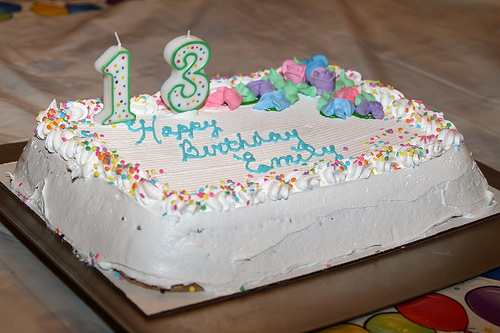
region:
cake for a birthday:
[11, 19, 494, 299]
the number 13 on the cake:
[91, 25, 211, 124]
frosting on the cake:
[233, 220, 367, 249]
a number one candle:
[91, 29, 139, 129]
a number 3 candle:
[158, 30, 216, 116]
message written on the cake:
[123, 113, 353, 171]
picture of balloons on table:
[363, 277, 499, 330]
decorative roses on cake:
[206, 54, 395, 120]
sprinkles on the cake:
[93, 143, 136, 180]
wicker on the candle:
[111, 33, 126, 46]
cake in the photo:
[48, 43, 460, 273]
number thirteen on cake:
[81, 21, 238, 140]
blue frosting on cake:
[134, 117, 345, 177]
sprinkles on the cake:
[95, 138, 172, 197]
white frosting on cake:
[234, 199, 325, 247]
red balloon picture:
[390, 288, 481, 330]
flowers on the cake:
[255, 56, 357, 124]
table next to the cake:
[311, 11, 429, 51]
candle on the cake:
[157, 20, 227, 117]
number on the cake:
[81, 29, 156, 133]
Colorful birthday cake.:
[3, 8, 498, 297]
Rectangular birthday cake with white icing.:
[9, 53, 499, 263]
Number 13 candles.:
[83, 26, 216, 128]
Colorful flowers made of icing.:
[206, 50, 406, 116]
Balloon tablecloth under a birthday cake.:
[320, 270, 496, 327]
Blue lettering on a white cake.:
[115, 112, 360, 181]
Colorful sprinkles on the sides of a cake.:
[29, 95, 211, 227]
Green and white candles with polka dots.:
[87, 25, 217, 128]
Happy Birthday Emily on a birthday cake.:
[120, 119, 352, 177]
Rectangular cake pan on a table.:
[1, 138, 498, 298]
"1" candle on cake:
[94, 38, 137, 130]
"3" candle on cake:
[161, 32, 210, 117]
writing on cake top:
[136, 117, 343, 172]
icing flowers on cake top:
[210, 50, 391, 126]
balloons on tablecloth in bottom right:
[312, 260, 494, 330]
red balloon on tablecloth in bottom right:
[395, 281, 461, 327]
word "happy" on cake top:
[122, 111, 222, 138]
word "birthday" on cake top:
[172, 126, 317, 151]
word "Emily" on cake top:
[235, 141, 350, 171]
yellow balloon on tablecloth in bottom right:
[365, 307, 425, 329]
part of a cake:
[387, 207, 409, 227]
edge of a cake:
[192, 247, 217, 287]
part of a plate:
[396, 285, 406, 291]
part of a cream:
[236, 102, 262, 161]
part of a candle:
[153, 64, 162, 104]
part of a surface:
[396, 58, 416, 76]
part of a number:
[116, 70, 133, 95]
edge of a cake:
[249, 199, 270, 226]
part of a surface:
[370, 288, 383, 305]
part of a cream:
[278, 199, 290, 211]